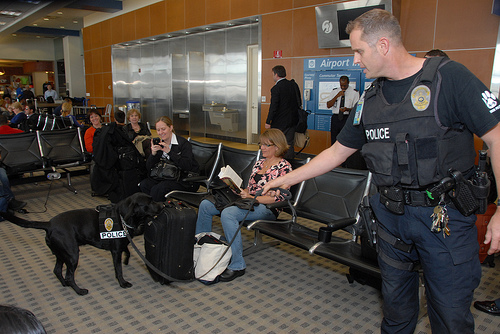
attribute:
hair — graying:
[347, 7, 401, 55]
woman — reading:
[193, 125, 294, 287]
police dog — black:
[0, 189, 164, 294]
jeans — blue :
[194, 188, 260, 270]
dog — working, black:
[2, 192, 163, 294]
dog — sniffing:
[12, 178, 184, 296]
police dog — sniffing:
[71, 190, 149, 262]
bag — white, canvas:
[182, 226, 243, 293]